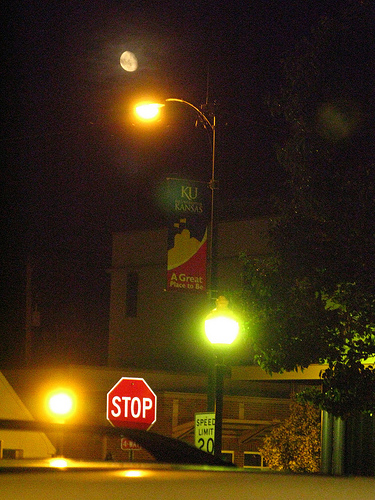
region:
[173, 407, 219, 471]
the speed limit is 20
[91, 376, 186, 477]
the sign is red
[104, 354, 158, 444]
the sign says STOP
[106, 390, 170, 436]
the text is white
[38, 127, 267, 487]
it is night time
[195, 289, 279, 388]
the lights are yellow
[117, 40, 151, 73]
the moon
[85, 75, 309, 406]
the lights are turned on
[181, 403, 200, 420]
the wall is bricked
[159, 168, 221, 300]
the ad poster is on a pole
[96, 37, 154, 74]
a bright moon over the city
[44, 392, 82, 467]
a bright street lamp shining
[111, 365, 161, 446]
a stop sign on the corner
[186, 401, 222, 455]
a speed marker sign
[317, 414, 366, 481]
a metal planter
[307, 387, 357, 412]
a green plant in the planter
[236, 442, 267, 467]
windows in a building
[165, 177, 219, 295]
a sign hanging on a post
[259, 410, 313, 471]
a shrub next to the street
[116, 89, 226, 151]
a street light on a tall arched pole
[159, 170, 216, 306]
vertical banner on pole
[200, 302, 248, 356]
glowing street lamp on pole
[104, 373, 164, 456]
stop sign on pole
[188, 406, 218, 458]
speed limit sign on pole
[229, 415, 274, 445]
awning on brick wall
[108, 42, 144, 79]
moon in night sky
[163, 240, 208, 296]
red swirl on banner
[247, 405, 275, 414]
wall of brick building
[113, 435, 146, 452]
small sign under stop sign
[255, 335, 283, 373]
light reflection on leaves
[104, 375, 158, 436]
a red and white stop sign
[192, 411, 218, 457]
a black and white sign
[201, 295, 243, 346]
a yellow street light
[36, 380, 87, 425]
an orange street light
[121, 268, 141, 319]
a window on the building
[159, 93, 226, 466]
a black street light pole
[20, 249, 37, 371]
a wooden telephone pole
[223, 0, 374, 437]
a green tree on the street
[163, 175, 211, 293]
a red white and blue banner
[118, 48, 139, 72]
the white moon in the sky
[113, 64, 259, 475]
lighted street lamp on corner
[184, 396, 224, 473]
speed limit sign on road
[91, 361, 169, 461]
stop sign at street corner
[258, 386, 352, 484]
bush beside street corner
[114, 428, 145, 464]
four way sign on pole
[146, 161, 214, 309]
red, white, and blue banner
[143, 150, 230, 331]
banner hanging from street light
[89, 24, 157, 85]
moon shining in night sky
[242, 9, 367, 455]
tall tree beside curb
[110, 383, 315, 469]
brick building across street